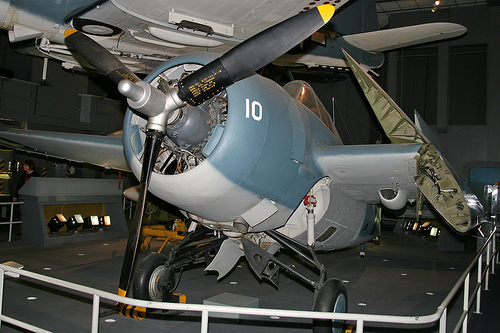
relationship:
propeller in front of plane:
[63, 4, 336, 299] [62, 5, 488, 332]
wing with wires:
[316, 45, 489, 236] [419, 146, 457, 199]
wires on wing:
[419, 146, 457, 199] [316, 45, 489, 236]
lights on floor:
[47, 207, 112, 234] [1, 219, 499, 333]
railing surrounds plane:
[0, 196, 498, 332] [62, 5, 488, 332]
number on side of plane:
[244, 94, 265, 126] [62, 5, 488, 332]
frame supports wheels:
[158, 194, 326, 313] [130, 251, 349, 332]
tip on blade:
[317, 1, 336, 23] [179, 2, 336, 107]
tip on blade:
[63, 27, 77, 37] [62, 27, 141, 84]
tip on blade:
[116, 287, 127, 297] [116, 127, 166, 298]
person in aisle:
[12, 161, 41, 202] [0, 179, 136, 243]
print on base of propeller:
[187, 68, 223, 98] [178, 57, 234, 109]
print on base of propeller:
[114, 67, 140, 85] [104, 65, 142, 84]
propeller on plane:
[63, 4, 336, 299] [62, 5, 488, 332]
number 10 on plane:
[244, 94, 265, 126] [62, 5, 488, 332]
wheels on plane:
[130, 251, 349, 332] [62, 5, 488, 332]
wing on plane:
[316, 45, 489, 236] [62, 5, 488, 332]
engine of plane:
[122, 53, 300, 230] [62, 5, 488, 332]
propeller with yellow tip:
[63, 4, 336, 299] [317, 1, 336, 23]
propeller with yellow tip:
[63, 4, 336, 299] [63, 27, 77, 37]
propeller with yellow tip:
[63, 4, 336, 299] [116, 287, 127, 297]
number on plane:
[244, 94, 265, 126] [62, 5, 488, 332]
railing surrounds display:
[0, 196, 498, 332] [1, 3, 498, 332]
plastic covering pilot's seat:
[281, 78, 342, 144] [307, 102, 320, 117]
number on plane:
[244, 97, 262, 120] [62, 5, 488, 332]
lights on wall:
[47, 207, 112, 234] [17, 176, 131, 251]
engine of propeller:
[122, 53, 300, 230] [63, 4, 336, 299]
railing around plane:
[0, 196, 498, 332] [62, 5, 488, 332]